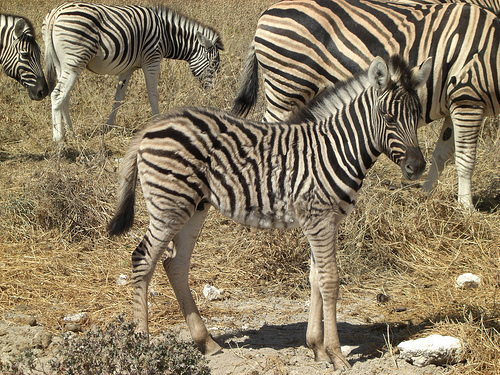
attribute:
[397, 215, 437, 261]
hay — dry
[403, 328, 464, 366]
rocks — white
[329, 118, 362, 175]
stripes — black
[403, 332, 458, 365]
rock — white 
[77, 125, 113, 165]
grass — dead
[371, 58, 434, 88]
ears — perked up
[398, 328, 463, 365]
rocks — white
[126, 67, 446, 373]
zebra — white 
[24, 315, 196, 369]
shrubbery — dead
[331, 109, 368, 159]
stripes — black, white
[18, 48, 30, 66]
eye — black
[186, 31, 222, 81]
head — bent 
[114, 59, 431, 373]
zebra — small, black, white, striped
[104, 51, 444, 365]
zebra — tiny, baby, striped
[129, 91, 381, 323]
stripes — white, black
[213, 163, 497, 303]
grass — dry